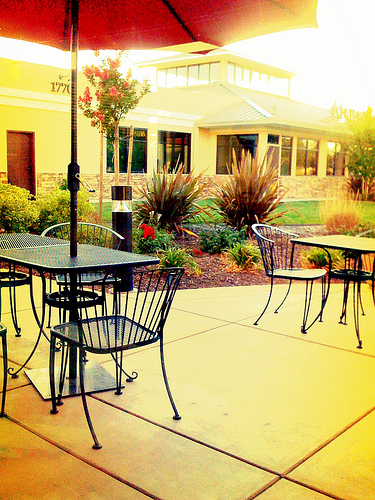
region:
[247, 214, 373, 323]
Two chairs are next to the table.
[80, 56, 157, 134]
The flowers are red.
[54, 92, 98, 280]
The umbrella goes through the table.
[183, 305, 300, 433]
The floor is made up of tile.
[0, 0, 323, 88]
The umbrella is open.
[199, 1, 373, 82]
It is very sunny outside.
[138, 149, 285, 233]
Two plants are next to each other.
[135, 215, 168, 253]
The flowers are red.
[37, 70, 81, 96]
The building has a number on it.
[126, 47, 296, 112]
The balcony is on top of the building.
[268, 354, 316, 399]
Tiled floor in the ground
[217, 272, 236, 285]
Small patch of dirt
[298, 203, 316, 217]
Small patch of green grass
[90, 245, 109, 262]
Small part of the black table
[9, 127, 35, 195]
Brown door that enters the building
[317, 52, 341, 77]
A clear white sky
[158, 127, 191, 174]
One of the windows in the building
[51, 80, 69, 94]
Numbers located in the building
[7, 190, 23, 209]
Small part of a green bush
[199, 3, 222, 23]
Bottom of the red umbrella that covers the table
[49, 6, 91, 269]
umbrella on a table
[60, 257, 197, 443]
chair in front of a table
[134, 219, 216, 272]
red flowers in the garden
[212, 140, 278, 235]
bush in the garden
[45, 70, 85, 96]
Number 1770 on a building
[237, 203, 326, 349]
green chair in front of a square table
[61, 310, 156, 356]
mesh wire on a chair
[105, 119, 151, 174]
glass on the building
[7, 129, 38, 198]
brown door on the building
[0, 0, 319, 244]
a red umbrella on a pole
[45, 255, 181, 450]
a black metal chair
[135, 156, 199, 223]
a tall glassy plant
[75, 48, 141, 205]
a green tree flowering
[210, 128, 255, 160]
a glass window on a building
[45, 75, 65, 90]
a number on a building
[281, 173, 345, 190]
a stone wall on a building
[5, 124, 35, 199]
a red door on a building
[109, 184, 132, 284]
a black pole with a light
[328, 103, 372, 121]
writing on top of a building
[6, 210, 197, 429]
chairs around a table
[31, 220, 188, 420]
chairs are made of metal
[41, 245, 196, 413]
chairs are black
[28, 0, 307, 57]
the unbrella is red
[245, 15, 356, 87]
sun is shining brightly in the sky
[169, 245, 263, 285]
red mulch in the garden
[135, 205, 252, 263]
short grassy plants growing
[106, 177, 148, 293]
black pole with a light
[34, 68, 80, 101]
address on the building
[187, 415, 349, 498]
cracks in the sidewalk